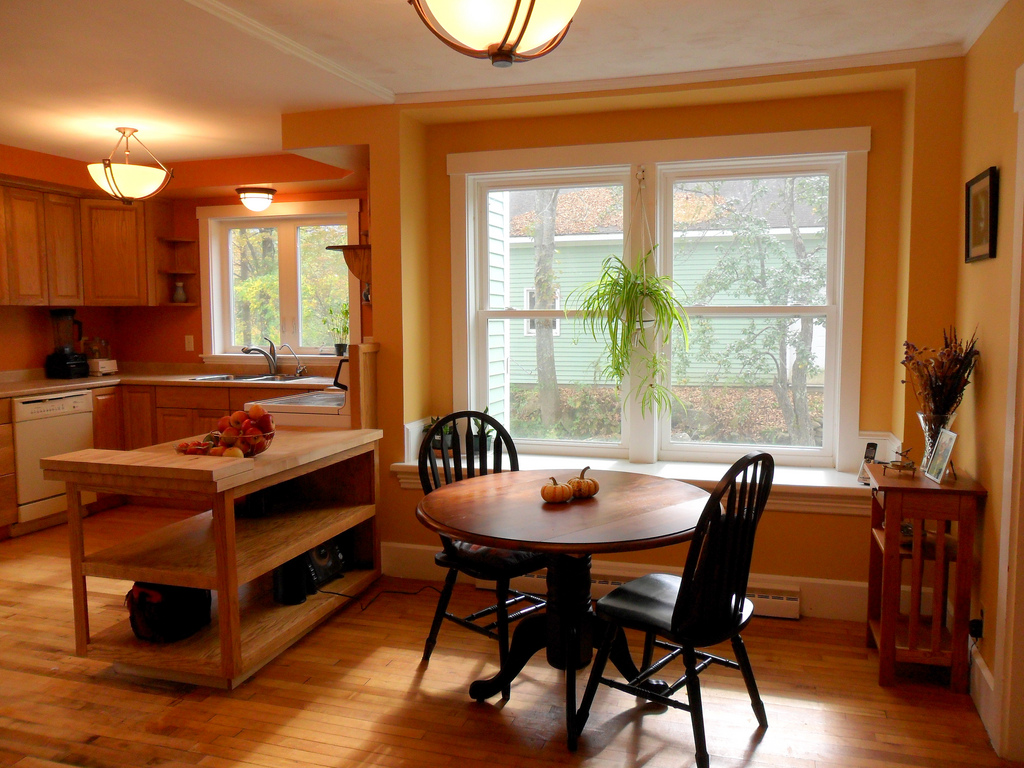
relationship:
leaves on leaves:
[571, 241, 688, 412] [564, 243, 692, 421]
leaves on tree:
[642, 323, 671, 410] [657, 158, 850, 429]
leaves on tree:
[716, 187, 773, 251] [668, 176, 839, 436]